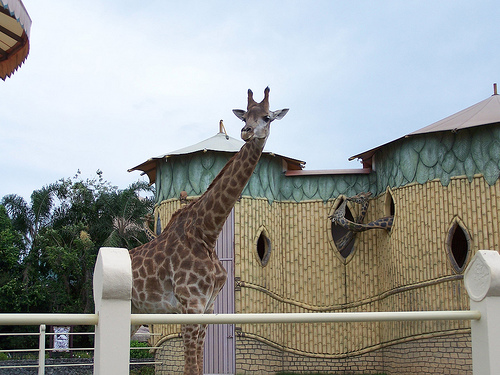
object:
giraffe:
[128, 85, 291, 375]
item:
[0, 0, 34, 82]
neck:
[165, 142, 269, 245]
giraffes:
[333, 189, 375, 258]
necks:
[339, 217, 395, 234]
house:
[125, 82, 499, 375]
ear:
[229, 107, 251, 120]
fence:
[0, 245, 499, 375]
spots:
[164, 231, 181, 258]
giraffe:
[326, 198, 394, 233]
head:
[344, 190, 375, 207]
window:
[330, 195, 360, 258]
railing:
[0, 309, 482, 326]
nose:
[239, 127, 254, 134]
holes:
[244, 126, 252, 132]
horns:
[259, 84, 271, 107]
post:
[37, 324, 47, 375]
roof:
[126, 118, 308, 187]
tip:
[216, 119, 226, 135]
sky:
[32, 0, 499, 82]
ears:
[269, 107, 290, 120]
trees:
[0, 167, 156, 319]